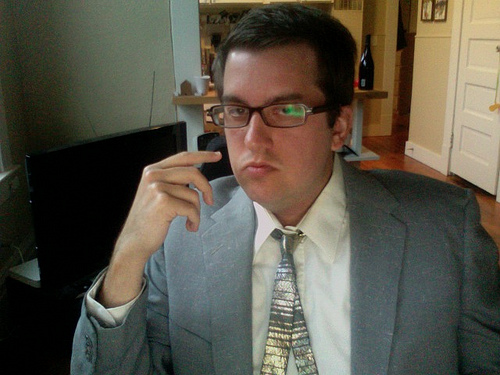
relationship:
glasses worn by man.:
[208, 100, 353, 129] [68, 4, 499, 374]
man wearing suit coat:
[68, 4, 499, 374] [71, 156, 500, 374]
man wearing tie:
[68, 4, 499, 374] [260, 228, 319, 374]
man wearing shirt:
[68, 4, 499, 374] [252, 151, 352, 374]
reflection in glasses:
[283, 104, 304, 117] [208, 100, 353, 129]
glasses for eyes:
[208, 100, 353, 129] [233, 107, 295, 115]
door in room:
[448, 0, 499, 198] [0, 2, 499, 286]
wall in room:
[0, 1, 174, 278] [0, 2, 499, 286]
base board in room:
[404, 140, 450, 177] [0, 2, 499, 286]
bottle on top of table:
[358, 33, 374, 92] [173, 87, 388, 168]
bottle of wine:
[358, 33, 374, 92] [359, 47, 374, 89]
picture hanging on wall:
[432, 0, 449, 23] [406, 1, 453, 157]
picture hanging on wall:
[419, 0, 433, 23] [0, 1, 174, 278]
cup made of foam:
[194, 74, 211, 97] [195, 75, 211, 97]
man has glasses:
[68, 4, 499, 374] [208, 100, 353, 129]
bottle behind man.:
[358, 33, 374, 92] [68, 4, 499, 374]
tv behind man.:
[21, 118, 189, 303] [68, 4, 499, 374]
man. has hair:
[68, 4, 499, 374] [212, 3, 355, 130]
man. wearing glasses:
[68, 4, 499, 374] [208, 100, 353, 129]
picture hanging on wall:
[419, 0, 433, 23] [406, 1, 453, 157]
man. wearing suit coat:
[68, 4, 499, 374] [71, 156, 500, 374]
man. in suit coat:
[68, 4, 499, 374] [71, 156, 500, 374]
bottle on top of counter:
[358, 33, 374, 92] [170, 80, 390, 105]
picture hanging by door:
[419, 0, 433, 23] [448, 0, 499, 198]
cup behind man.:
[194, 74, 211, 97] [68, 4, 499, 374]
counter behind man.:
[170, 80, 390, 105] [68, 4, 499, 374]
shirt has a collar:
[252, 151, 352, 374] [252, 153, 345, 268]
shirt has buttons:
[252, 151, 352, 374] [295, 234, 307, 374]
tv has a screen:
[21, 118, 189, 303] [25, 121, 187, 295]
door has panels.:
[448, 0, 499, 198] [459, 3, 499, 169]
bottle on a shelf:
[358, 33, 374, 92] [170, 80, 390, 105]